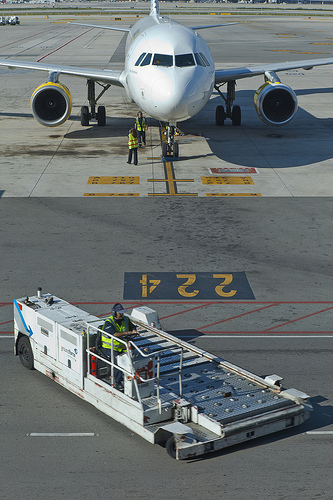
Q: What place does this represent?
A: It represents the pavement.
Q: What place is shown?
A: It is a pavement.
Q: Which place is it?
A: It is a pavement.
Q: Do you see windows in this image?
A: Yes, there is a window.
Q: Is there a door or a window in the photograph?
A: Yes, there is a window.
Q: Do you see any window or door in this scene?
A: Yes, there is a window.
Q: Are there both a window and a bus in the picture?
A: No, there is a window but no buses.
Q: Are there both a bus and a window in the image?
A: No, there is a window but no buses.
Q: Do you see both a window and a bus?
A: No, there is a window but no buses.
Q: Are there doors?
A: No, there are no doors.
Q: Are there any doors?
A: No, there are no doors.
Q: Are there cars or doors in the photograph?
A: No, there are no doors or cars.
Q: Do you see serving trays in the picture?
A: No, there are no serving trays.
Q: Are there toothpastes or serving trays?
A: No, there are no serving trays or toothpastes.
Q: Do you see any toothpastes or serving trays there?
A: No, there are no serving trays or toothpastes.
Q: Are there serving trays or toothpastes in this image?
A: No, there are no serving trays or toothpastes.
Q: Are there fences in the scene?
A: No, there are no fences.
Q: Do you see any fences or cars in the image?
A: No, there are no fences or cars.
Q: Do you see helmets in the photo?
A: No, there are no helmets.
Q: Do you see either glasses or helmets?
A: No, there are no helmets or glasses.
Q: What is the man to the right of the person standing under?
A: The man is standing under the airplane.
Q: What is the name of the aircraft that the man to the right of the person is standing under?
A: The aircraft is an airplane.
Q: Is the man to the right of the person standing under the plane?
A: Yes, the man is standing under the plane.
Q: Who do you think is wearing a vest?
A: The man is wearing a vest.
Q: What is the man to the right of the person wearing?
A: The man is wearing a vest.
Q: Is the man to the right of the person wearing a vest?
A: Yes, the man is wearing a vest.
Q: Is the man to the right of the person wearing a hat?
A: No, the man is wearing a vest.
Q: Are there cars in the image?
A: No, there are no cars.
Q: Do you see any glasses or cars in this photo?
A: No, there are no cars or glasses.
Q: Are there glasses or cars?
A: No, there are no cars or glasses.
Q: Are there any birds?
A: No, there are no birds.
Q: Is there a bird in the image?
A: No, there are no birds.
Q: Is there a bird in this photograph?
A: No, there are no birds.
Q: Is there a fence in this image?
A: No, there are no fences.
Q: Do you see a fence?
A: No, there are no fences.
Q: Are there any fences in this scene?
A: No, there are no fences.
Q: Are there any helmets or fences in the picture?
A: No, there are no fences or helmets.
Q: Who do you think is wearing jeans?
A: The man is wearing jeans.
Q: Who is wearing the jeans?
A: The man is wearing jeans.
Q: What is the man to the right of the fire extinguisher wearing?
A: The man is wearing jeans.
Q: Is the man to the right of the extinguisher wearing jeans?
A: Yes, the man is wearing jeans.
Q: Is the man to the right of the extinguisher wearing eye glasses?
A: No, the man is wearing jeans.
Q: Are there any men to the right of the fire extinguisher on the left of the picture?
A: Yes, there is a man to the right of the extinguisher.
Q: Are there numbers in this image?
A: Yes, there are numbers.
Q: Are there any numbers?
A: Yes, there are numbers.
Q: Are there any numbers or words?
A: Yes, there are numbers.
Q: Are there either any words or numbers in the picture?
A: Yes, there are numbers.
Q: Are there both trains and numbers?
A: No, there are numbers but no trains.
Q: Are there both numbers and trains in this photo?
A: No, there are numbers but no trains.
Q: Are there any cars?
A: No, there are no cars.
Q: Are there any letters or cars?
A: No, there are no cars or letters.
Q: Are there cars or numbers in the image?
A: Yes, there are numbers.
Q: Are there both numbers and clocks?
A: No, there are numbers but no clocks.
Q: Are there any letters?
A: No, there are no letters.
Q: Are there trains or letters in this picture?
A: No, there are no letters or trains.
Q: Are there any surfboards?
A: No, there are no surfboards.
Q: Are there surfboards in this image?
A: No, there are no surfboards.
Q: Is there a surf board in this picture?
A: No, there are no surfboards.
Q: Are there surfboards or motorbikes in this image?
A: No, there are no surfboards or motorbikes.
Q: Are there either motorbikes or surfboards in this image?
A: No, there are no surfboards or motorbikes.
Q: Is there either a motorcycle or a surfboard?
A: No, there are no surfboards or motorcycles.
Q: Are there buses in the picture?
A: No, there are no buses.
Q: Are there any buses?
A: No, there are no buses.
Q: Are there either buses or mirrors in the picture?
A: No, there are no buses or mirrors.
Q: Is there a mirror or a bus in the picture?
A: No, there are no buses or mirrors.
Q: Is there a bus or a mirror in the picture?
A: No, there are no buses or mirrors.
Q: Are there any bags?
A: No, there are no bags.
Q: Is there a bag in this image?
A: No, there are no bags.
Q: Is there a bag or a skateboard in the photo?
A: No, there are no bags or skateboards.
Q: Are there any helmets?
A: No, there are no helmets.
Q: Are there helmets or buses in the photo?
A: No, there are no helmets or buses.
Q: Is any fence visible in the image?
A: No, there are no fences.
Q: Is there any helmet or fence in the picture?
A: No, there are no fences or helmets.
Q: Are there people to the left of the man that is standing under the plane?
A: Yes, there is a person to the left of the man.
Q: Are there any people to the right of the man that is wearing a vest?
A: No, the person is to the left of the man.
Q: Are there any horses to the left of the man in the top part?
A: No, there is a person to the left of the man.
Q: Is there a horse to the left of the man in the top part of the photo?
A: No, there is a person to the left of the man.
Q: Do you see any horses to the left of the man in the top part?
A: No, there is a person to the left of the man.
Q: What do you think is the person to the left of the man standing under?
A: The person is standing under the plane.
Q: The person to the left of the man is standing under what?
A: The person is standing under the plane.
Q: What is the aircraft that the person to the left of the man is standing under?
A: The aircraft is an airplane.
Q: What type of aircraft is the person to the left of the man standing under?
A: The person is standing under the plane.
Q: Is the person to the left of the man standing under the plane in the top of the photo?
A: Yes, the person is standing under the airplane.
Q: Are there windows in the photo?
A: Yes, there is a window.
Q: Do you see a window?
A: Yes, there is a window.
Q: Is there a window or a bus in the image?
A: Yes, there is a window.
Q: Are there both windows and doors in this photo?
A: No, there is a window but no doors.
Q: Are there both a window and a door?
A: No, there is a window but no doors.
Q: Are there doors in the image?
A: No, there are no doors.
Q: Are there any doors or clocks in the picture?
A: No, there are no doors or clocks.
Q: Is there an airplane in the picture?
A: Yes, there is an airplane.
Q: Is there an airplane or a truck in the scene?
A: Yes, there is an airplane.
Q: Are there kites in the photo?
A: No, there are no kites.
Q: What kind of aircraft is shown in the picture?
A: The aircraft is an airplane.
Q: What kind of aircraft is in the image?
A: The aircraft is an airplane.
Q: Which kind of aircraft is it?
A: The aircraft is an airplane.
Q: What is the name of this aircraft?
A: This is an airplane.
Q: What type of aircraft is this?
A: This is an airplane.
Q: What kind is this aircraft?
A: This is an airplane.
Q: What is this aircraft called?
A: This is an airplane.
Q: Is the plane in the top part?
A: Yes, the plane is in the top of the image.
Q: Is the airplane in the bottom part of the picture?
A: No, the airplane is in the top of the image.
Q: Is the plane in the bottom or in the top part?
A: The plane is in the top of the image.